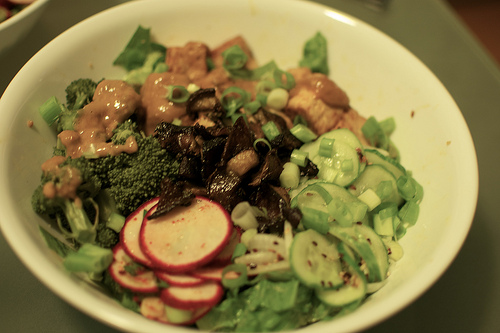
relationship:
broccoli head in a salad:
[88, 132, 188, 209] [31, 22, 421, 330]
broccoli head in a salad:
[63, 77, 95, 113] [31, 22, 421, 330]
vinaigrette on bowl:
[73, 70, 198, 202] [0, 3, 481, 330]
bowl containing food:
[0, 0, 52, 46] [30, 25, 424, 331]